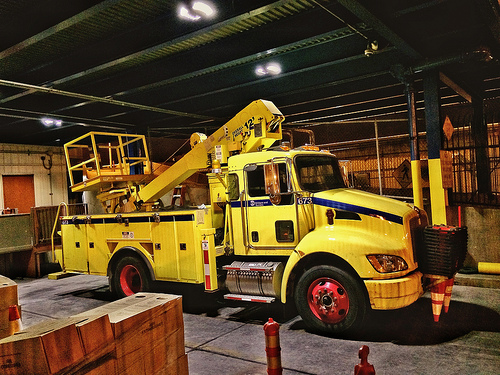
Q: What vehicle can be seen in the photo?
A: A truck.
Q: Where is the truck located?
A: In a garage.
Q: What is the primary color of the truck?
A: Yellow.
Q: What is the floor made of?
A: Concrete.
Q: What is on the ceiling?
A: Lights.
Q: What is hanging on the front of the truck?
A: Safety cones.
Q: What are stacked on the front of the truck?
A: Cones.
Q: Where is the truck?
A: Garage.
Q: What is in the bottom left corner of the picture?
A: Boxes.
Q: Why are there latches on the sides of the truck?
A: Doors.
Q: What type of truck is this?
A: Lift truck.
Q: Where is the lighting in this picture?
A: Ceiling.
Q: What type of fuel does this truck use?
A: Diesel.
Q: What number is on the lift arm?
A: 12.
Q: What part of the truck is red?
A: Wheels.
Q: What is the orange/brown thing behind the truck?
A: Door.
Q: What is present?
A: A truck.